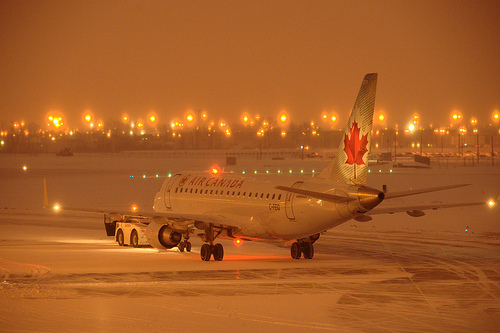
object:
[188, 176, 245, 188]
name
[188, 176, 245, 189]
red writing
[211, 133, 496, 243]
overhead light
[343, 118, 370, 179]
red leaf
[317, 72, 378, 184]
tail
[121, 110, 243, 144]
houses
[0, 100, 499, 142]
lights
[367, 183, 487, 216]
wing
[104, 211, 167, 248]
car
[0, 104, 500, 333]
airport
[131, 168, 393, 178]
lights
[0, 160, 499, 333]
runway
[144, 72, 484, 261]
aeroplane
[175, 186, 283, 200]
window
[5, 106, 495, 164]
vista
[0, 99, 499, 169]
distance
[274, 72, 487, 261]
back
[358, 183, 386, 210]
tip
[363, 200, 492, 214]
left wing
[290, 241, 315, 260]
wheel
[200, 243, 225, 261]
wheel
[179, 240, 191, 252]
wheel